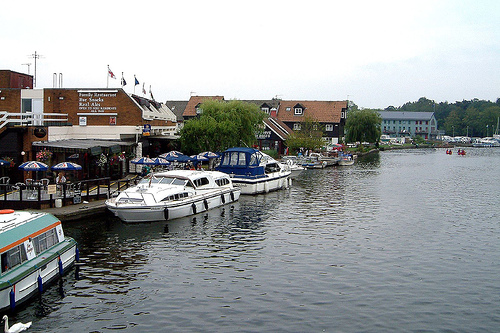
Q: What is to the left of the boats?
A: Restaurant.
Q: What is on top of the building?
A: Flags.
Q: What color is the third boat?
A: Blue.